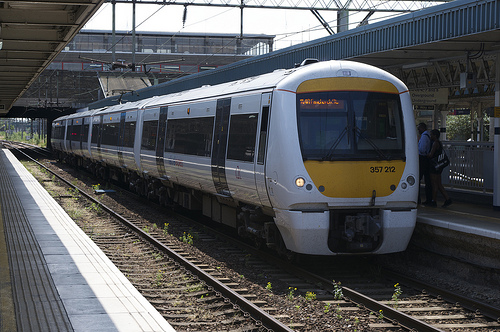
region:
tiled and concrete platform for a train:
[0, 140, 147, 328]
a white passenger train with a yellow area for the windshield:
[46, 60, 413, 255]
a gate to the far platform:
[444, 133, 499, 201]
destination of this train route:
[296, 90, 343, 112]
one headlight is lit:
[291, 173, 421, 188]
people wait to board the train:
[416, 113, 451, 209]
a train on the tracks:
[222, 58, 435, 329]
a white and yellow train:
[184, 43, 489, 315]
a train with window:
[301, 98, 360, 172]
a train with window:
[357, 93, 439, 168]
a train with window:
[232, 122, 254, 168]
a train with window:
[187, 119, 213, 152]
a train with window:
[168, 117, 186, 166]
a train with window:
[124, 113, 133, 147]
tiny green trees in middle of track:
[252, 270, 341, 316]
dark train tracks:
[151, 233, 292, 329]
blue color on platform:
[49, 249, 101, 321]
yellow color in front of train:
[290, 145, 417, 205]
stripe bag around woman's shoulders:
[431, 141, 457, 176]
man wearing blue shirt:
[414, 125, 436, 158]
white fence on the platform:
[437, 130, 497, 194]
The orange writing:
[289, 82, 342, 122]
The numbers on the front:
[361, 151, 408, 171]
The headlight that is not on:
[391, 165, 431, 198]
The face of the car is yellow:
[289, 65, 414, 197]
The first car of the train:
[154, 56, 422, 257]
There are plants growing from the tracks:
[154, 213, 205, 250]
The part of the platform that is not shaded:
[4, 141, 171, 329]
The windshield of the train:
[293, 82, 412, 163]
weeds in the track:
[140, 198, 387, 328]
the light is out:
[395, 167, 418, 209]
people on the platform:
[420, 123, 455, 217]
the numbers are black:
[365, 160, 406, 176]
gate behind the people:
[410, 123, 498, 215]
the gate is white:
[440, 142, 490, 207]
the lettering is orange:
[298, 89, 351, 114]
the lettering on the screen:
[297, 94, 344, 114]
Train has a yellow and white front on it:
[272, 59, 431, 277]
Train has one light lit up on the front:
[293, 173, 306, 185]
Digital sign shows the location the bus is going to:
[290, 92, 352, 111]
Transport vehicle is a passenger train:
[39, 56, 441, 263]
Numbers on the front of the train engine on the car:
[254, 53, 436, 234]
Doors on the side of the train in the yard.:
[48, 98, 276, 208]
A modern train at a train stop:
[48, 52, 420, 260]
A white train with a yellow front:
[38, 56, 418, 256]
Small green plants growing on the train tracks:
[262, 269, 349, 316]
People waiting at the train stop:
[412, 117, 452, 214]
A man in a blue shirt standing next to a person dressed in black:
[413, 119, 434, 196]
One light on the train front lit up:
[288, 176, 306, 186]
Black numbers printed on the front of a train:
[369, 155, 395, 175]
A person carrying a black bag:
[426, 125, 457, 210]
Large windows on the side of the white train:
[41, 106, 264, 171]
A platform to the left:
[1, 141, 173, 324]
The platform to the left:
[0, 135, 182, 328]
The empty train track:
[2, 136, 309, 329]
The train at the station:
[34, 56, 424, 293]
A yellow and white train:
[24, 58, 439, 268]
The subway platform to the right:
[416, 178, 498, 239]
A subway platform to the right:
[422, 184, 498, 246]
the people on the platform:
[411, 111, 471, 204]